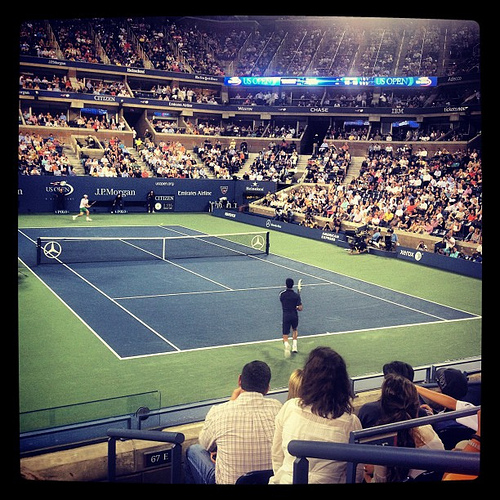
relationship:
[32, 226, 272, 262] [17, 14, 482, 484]
net to arena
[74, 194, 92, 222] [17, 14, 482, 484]
player on arena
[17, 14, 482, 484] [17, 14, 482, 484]
arena in arena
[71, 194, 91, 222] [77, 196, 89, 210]
player wearing shirt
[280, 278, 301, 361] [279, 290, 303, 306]
man wearing shirt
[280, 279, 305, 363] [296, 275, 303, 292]
man holding bat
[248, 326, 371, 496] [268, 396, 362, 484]
lady wearing shirt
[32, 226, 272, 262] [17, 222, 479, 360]
net on tennis court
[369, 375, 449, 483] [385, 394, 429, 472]
spectators wearing ponytail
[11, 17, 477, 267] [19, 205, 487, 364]
spectator at tennis match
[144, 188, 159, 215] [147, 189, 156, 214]
boy in boy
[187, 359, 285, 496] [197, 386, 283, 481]
man in plaid shirt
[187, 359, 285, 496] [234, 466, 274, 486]
man in blue jeans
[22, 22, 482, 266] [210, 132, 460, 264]
seating with spectators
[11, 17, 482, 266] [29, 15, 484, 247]
spectator in stands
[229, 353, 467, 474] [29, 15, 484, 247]
spectators in stands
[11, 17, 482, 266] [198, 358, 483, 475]
spectator in stands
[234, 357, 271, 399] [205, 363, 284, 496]
head on man